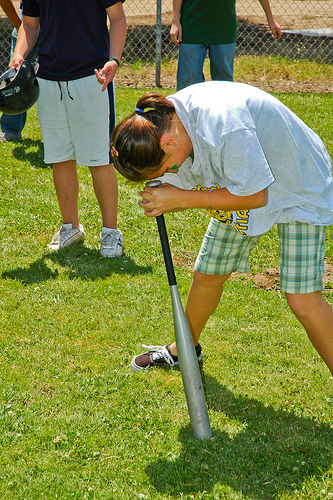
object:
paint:
[170, 164, 178, 171]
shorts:
[193, 219, 328, 296]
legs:
[275, 220, 333, 379]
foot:
[98, 224, 124, 261]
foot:
[44, 217, 85, 253]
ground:
[0, 0, 333, 498]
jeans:
[176, 40, 238, 96]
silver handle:
[144, 177, 162, 189]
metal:
[185, 353, 197, 405]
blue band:
[132, 104, 145, 116]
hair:
[108, 89, 175, 185]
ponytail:
[135, 88, 176, 115]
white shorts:
[35, 69, 112, 169]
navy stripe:
[106, 80, 116, 165]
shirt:
[178, 0, 240, 51]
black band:
[106, 55, 120, 67]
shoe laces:
[140, 343, 175, 370]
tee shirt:
[149, 77, 333, 241]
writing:
[234, 209, 250, 239]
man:
[8, 0, 130, 262]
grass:
[0, 52, 333, 498]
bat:
[145, 177, 216, 443]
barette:
[109, 144, 120, 159]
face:
[141, 140, 194, 180]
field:
[0, 0, 333, 499]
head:
[109, 89, 193, 184]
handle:
[144, 178, 177, 287]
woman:
[108, 76, 333, 380]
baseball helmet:
[0, 58, 41, 118]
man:
[169, 1, 284, 96]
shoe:
[129, 338, 204, 378]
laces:
[98, 227, 121, 250]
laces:
[49, 223, 74, 248]